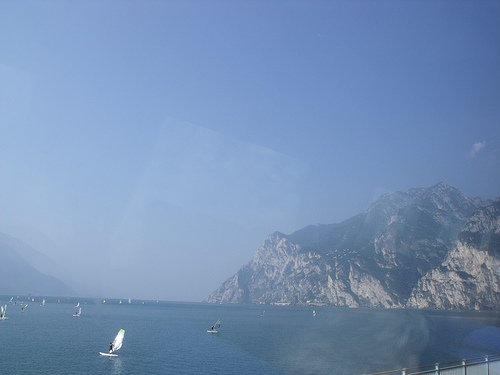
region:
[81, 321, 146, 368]
boat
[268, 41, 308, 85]
white clouds in blue sky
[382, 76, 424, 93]
white clouds in blue sky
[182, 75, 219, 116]
white clouds in blue sky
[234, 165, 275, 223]
white clouds in blue sky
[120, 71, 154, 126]
white clouds in blue sky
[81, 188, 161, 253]
white clouds in blue sky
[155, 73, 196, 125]
white clouds in blue sky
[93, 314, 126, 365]
white boat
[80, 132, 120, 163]
white clouds in blue sky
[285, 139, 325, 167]
white clouds in blue sky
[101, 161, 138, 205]
white clouds in blue sky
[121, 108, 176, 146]
white clouds in blue sky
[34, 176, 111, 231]
white clouds in blue sky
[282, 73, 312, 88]
white clouds in blue sky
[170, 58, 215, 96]
white clouds in blue sky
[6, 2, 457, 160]
a clear blue sky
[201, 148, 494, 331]
a mountain towering over the ocean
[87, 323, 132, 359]
a windsurfer on the ocean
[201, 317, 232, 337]
a windsurfer on the water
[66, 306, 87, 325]
a windsurfer on the water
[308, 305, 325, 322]
a windsurfer on the water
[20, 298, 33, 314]
a windsurfer on the water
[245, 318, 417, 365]
clear blue ocean water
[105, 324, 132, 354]
a white windsurfer sail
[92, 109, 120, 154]
white clouds in blue sky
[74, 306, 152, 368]
boat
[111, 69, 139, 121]
white clouds in blue sky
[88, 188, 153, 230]
white clouds in blue sky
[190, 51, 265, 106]
vwhite clouds in blue sky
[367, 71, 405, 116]
white clouds in blue sky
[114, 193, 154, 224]
white clouds in blue sky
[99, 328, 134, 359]
bird on top of water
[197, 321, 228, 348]
bird on top of water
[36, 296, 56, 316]
bird on top of water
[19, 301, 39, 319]
bird on top of water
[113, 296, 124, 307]
bird on top of water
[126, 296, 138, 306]
bird on top of water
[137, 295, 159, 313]
bird on top of water